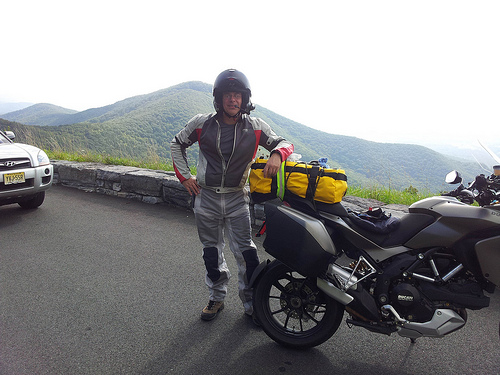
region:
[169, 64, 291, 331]
Man wearing gray jacket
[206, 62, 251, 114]
Black helmet on man's head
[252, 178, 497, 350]
Motorcycle on the road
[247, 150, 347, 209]
Yellow bag on motorcycle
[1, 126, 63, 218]
Silver vehicle behind man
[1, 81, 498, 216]
Mountains in the background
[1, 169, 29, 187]
License plate on front of vehicle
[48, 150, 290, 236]
Border made of brick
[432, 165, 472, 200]
Side mirror on bike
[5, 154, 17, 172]
Honda logo on car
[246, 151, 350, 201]
Yellow bag on the motorcycle.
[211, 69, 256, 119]
Helmet on the man's head.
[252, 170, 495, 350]
Silver, gray, and black motorcycle.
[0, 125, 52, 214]
Car on the road.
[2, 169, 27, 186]
License plate on the car.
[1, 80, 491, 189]
Mountains in the background.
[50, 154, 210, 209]
Short stone wall along side the road.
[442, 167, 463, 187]
Review mirror on the motorcycle.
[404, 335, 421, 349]
Kickstand on the motorcycle.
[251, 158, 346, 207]
Black straps on the bag.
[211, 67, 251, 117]
The man is wearing a black helmet.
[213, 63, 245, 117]
The man has on glasses.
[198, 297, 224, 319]
The man is wearing black and brown shoes.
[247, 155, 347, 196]
The man is leaning on a black and yellow bag.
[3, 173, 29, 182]
The license plate is yellow and black.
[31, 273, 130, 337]
The pavement in the forefront is gray.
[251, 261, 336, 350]
The back wheel is black in color.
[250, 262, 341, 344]
The back wheel is round.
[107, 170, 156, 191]
The road trim is made from stone.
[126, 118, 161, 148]
The hill in the background is green.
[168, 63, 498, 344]
a man standing beside a motorcycle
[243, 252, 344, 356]
the rear wheel of a motorcycle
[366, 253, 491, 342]
the engine of a motorcycle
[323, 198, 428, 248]
the seat of a motorcycle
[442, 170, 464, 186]
the mirror of a motorcycle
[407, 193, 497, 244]
the gas tank of a motorcycle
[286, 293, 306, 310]
the rear axle of a motorcycle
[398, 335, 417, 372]
the kickstand of a motorcycle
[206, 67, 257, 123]
a man wearing a helmet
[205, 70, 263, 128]
a man wearing glasses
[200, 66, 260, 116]
Black helmet on motorcycle rider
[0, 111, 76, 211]
Small Suv on the road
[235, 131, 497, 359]
Black and silver motorcycle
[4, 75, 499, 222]
Mountains in the distance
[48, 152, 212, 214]
Stone wall for road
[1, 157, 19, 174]
Silver Hyundai logo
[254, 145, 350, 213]
Yellow and black duffel bag on bike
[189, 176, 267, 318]
Silver pants on motorcycle rider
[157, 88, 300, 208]
Grey, Silver and red jacket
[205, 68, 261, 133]
Man looking at the camera